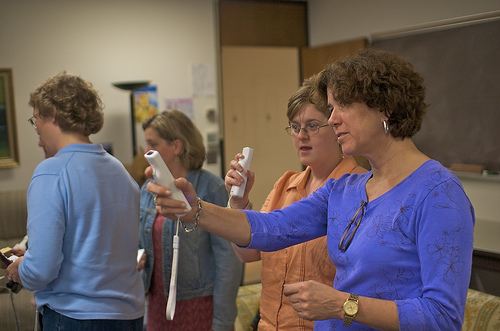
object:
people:
[5, 69, 145, 331]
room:
[1, 0, 500, 331]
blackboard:
[370, 9, 500, 185]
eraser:
[483, 169, 490, 174]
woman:
[222, 73, 369, 331]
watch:
[341, 289, 360, 327]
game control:
[230, 146, 254, 199]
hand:
[224, 152, 255, 199]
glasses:
[338, 200, 368, 252]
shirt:
[237, 159, 474, 331]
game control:
[144, 149, 193, 218]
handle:
[166, 235, 180, 321]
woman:
[141, 47, 474, 331]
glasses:
[285, 122, 329, 137]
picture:
[0, 67, 21, 171]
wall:
[0, 0, 307, 240]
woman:
[137, 109, 244, 331]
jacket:
[137, 168, 243, 331]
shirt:
[18, 143, 146, 321]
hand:
[144, 165, 199, 223]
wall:
[299, 0, 500, 300]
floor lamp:
[110, 81, 152, 159]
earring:
[383, 120, 389, 133]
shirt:
[226, 153, 371, 331]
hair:
[307, 45, 433, 141]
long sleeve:
[18, 157, 66, 291]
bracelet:
[179, 196, 203, 233]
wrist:
[187, 198, 211, 229]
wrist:
[338, 291, 361, 320]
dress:
[145, 213, 237, 331]